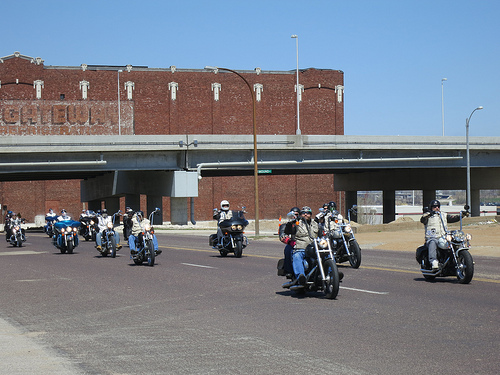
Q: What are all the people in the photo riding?
A: Motorcycles.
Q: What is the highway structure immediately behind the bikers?
A: Overpass.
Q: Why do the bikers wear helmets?
A: Protection.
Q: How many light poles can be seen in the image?
A: Five.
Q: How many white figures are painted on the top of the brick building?
A: Eight.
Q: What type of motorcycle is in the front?
A: Chopper.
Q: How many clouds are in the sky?
A: None.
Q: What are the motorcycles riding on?
A: Highway.